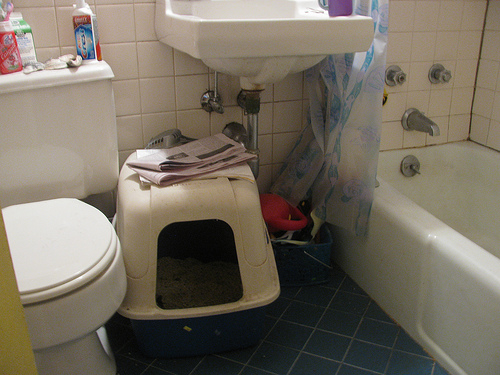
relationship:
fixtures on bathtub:
[384, 63, 451, 177] [337, 140, 500, 375]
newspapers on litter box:
[133, 133, 256, 186] [113, 148, 278, 353]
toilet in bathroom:
[2, 59, 132, 373] [4, 0, 498, 373]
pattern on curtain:
[316, 64, 344, 137] [271, 17, 406, 231]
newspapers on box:
[124, 133, 257, 186] [113, 149, 281, 320]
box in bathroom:
[113, 149, 281, 320] [4, 0, 498, 373]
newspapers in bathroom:
[124, 133, 257, 186] [4, 0, 498, 373]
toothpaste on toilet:
[70, 0, 97, 60] [2, 59, 132, 373]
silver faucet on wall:
[405, 107, 442, 138] [1, 0, 468, 142]